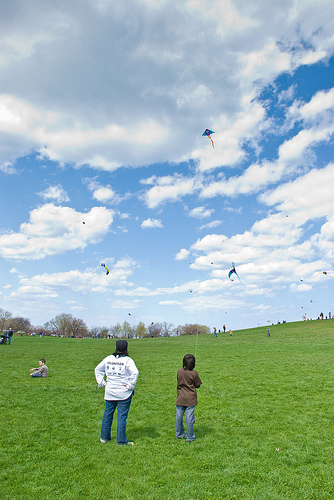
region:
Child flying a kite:
[168, 349, 211, 443]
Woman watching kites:
[89, 335, 151, 457]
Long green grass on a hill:
[220, 341, 301, 436]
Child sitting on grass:
[20, 354, 57, 387]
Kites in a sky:
[90, 248, 263, 302]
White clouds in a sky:
[44, 220, 321, 322]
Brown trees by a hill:
[52, 301, 223, 338]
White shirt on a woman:
[91, 350, 143, 407]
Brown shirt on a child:
[170, 360, 213, 414]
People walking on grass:
[198, 306, 294, 351]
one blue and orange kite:
[174, 106, 253, 184]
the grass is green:
[249, 373, 323, 442]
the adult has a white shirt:
[72, 323, 256, 482]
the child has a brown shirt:
[79, 331, 235, 475]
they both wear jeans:
[84, 329, 234, 458]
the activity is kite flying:
[76, 330, 250, 460]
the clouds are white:
[66, 123, 272, 299]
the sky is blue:
[145, 237, 175, 257]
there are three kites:
[51, 111, 259, 316]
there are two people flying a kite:
[58, 296, 234, 463]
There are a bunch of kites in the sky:
[45, 113, 333, 341]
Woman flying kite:
[173, 353, 205, 455]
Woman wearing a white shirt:
[86, 338, 156, 462]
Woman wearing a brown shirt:
[171, 354, 207, 449]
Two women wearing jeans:
[89, 337, 222, 458]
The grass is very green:
[5, 317, 330, 498]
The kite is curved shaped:
[95, 259, 120, 284]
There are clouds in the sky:
[8, 176, 332, 323]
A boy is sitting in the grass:
[28, 357, 54, 385]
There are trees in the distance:
[2, 309, 222, 349]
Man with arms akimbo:
[89, 332, 144, 396]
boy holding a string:
[170, 336, 212, 398]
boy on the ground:
[23, 353, 56, 383]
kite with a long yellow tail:
[188, 113, 231, 164]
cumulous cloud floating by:
[4, 189, 116, 260]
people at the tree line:
[37, 304, 105, 345]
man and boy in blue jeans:
[86, 390, 210, 450]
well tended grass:
[231, 408, 323, 470]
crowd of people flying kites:
[203, 255, 332, 338]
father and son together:
[91, 305, 213, 449]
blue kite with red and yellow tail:
[194, 126, 222, 146]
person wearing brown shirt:
[168, 352, 197, 442]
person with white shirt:
[90, 329, 135, 443]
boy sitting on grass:
[22, 351, 52, 379]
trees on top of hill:
[7, 309, 205, 341]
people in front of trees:
[6, 320, 142, 337]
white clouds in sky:
[51, 130, 119, 156]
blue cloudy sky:
[98, 180, 257, 328]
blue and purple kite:
[223, 261, 242, 280]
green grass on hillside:
[231, 351, 274, 451]